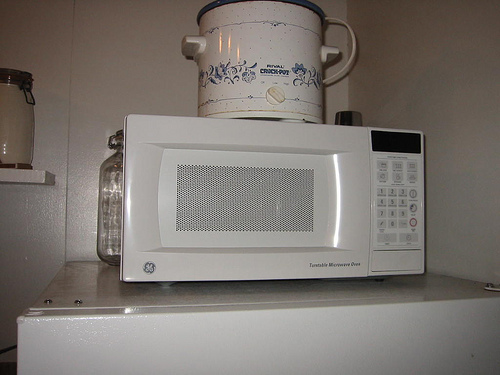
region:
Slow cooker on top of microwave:
[171, 3, 356, 125]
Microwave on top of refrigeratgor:
[119, 114, 458, 285]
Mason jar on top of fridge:
[95, 130, 125, 274]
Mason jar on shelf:
[2, 59, 42, 181]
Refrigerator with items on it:
[64, 291, 487, 366]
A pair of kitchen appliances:
[112, 3, 444, 298]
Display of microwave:
[371, 120, 430, 167]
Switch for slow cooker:
[259, 78, 293, 109]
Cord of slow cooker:
[318, 8, 365, 94]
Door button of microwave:
[367, 239, 435, 278]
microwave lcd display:
[365, 131, 428, 156]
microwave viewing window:
[168, 164, 319, 234]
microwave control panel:
[371, 157, 422, 249]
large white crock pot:
[180, 0, 356, 114]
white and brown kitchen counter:
[15, 257, 497, 369]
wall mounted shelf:
[2, 160, 54, 190]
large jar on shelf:
[0, 56, 37, 171]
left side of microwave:
[88, 116, 128, 287]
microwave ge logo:
[140, 253, 165, 283]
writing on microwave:
[303, 254, 367, 279]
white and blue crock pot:
[181, 2, 363, 118]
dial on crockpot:
[261, 85, 289, 105]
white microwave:
[121, 107, 428, 282]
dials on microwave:
[375, 154, 418, 268]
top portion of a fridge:
[13, 279, 498, 370]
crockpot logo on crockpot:
[258, 61, 296, 81]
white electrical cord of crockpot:
[324, 12, 359, 94]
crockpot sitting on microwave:
[116, 2, 432, 283]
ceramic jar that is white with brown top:
[0, 63, 42, 165]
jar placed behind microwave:
[98, 125, 128, 269]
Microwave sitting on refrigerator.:
[117, 111, 453, 290]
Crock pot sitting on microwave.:
[183, 1, 350, 122]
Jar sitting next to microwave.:
[88, 126, 120, 266]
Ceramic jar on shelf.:
[1, 68, 50, 172]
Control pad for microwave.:
[373, 154, 422, 250]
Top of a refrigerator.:
[21, 279, 498, 343]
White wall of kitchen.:
[52, 26, 89, 244]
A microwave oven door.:
[120, 115, 370, 280]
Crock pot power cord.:
[327, 16, 361, 91]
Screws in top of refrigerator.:
[43, 291, 90, 311]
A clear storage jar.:
[84, 118, 131, 268]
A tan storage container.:
[3, 47, 46, 174]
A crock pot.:
[180, 2, 360, 119]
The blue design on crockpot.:
[179, 26, 263, 92]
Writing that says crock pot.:
[253, 49, 297, 84]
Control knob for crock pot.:
[253, 75, 304, 116]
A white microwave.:
[122, 104, 431, 289]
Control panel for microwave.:
[370, 152, 420, 257]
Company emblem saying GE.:
[135, 255, 167, 280]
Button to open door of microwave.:
[361, 237, 434, 279]